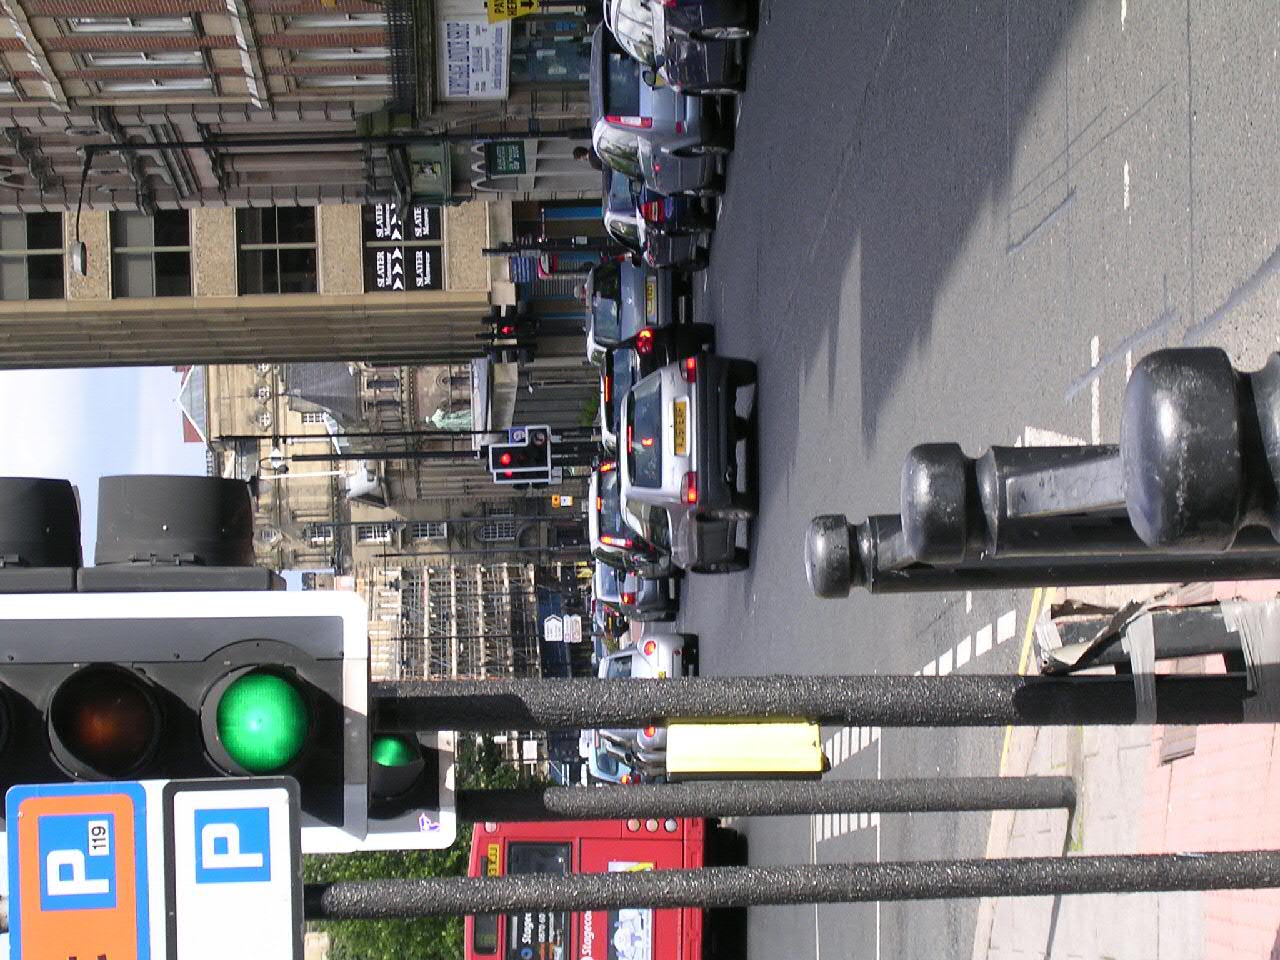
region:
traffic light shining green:
[204, 662, 324, 777]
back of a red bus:
[438, 821, 712, 958]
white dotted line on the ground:
[784, 601, 1036, 776]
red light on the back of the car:
[680, 353, 703, 378]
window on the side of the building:
[221, 190, 338, 294]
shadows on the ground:
[639, 2, 1116, 462]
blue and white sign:
[157, 777, 314, 958]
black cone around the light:
[89, 473, 270, 566]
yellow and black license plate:
[663, 395, 703, 468]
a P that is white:
[38, 853, 125, 906]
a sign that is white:
[148, 791, 312, 955]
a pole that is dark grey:
[292, 851, 1255, 911]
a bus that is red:
[449, 818, 717, 951]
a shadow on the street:
[755, 69, 1009, 361]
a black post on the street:
[729, 476, 1253, 605]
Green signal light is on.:
[202, 652, 346, 803]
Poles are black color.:
[430, 418, 1232, 915]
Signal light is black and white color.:
[11, 465, 416, 911]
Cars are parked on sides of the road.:
[531, 6, 730, 393]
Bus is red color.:
[443, 809, 726, 957]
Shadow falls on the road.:
[538, 23, 1154, 425]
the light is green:
[196, 643, 331, 791]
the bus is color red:
[432, 785, 730, 956]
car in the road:
[518, 304, 775, 680]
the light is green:
[372, 699, 448, 823]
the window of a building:
[0, 195, 93, 317]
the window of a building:
[97, 206, 206, 310]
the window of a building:
[222, 191, 337, 298]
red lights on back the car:
[661, 339, 726, 512]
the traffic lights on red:
[470, 420, 577, 502]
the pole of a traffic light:
[300, 593, 1278, 841]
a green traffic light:
[182, 641, 330, 776]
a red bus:
[444, 800, 747, 951]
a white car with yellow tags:
[576, 354, 795, 575]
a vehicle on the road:
[595, 371, 761, 530]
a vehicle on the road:
[550, 454, 687, 589]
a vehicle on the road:
[562, 496, 688, 655]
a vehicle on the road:
[577, 649, 712, 740]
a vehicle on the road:
[559, 240, 697, 366]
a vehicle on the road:
[608, 29, 714, 60]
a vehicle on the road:
[506, 505, 626, 609]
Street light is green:
[200, 660, 328, 795]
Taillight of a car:
[672, 355, 706, 400]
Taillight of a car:
[682, 463, 713, 510]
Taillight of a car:
[600, 106, 671, 142]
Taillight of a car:
[629, 642, 672, 665]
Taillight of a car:
[622, 331, 665, 358]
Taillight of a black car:
[626, 322, 671, 365]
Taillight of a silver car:
[668, 461, 711, 519]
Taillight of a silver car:
[670, 355, 713, 384]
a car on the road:
[566, 390, 748, 532]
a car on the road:
[570, 455, 679, 561]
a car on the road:
[596, 605, 672, 703]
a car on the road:
[530, 126, 705, 319]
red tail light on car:
[684, 468, 702, 504]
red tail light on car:
[595, 456, 616, 477]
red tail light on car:
[617, 591, 637, 611]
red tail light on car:
[642, 637, 658, 655]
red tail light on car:
[639, 724, 657, 742]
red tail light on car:
[640, 201, 661, 226]